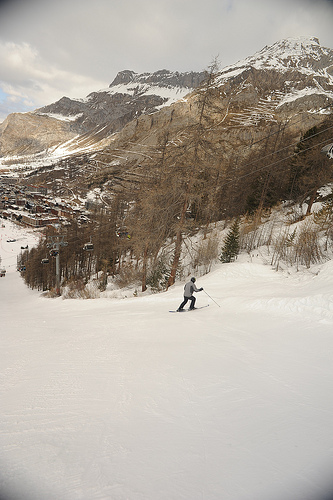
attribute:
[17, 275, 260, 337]
slope — ski  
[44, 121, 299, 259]
trees — Many 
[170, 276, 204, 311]
person — skiing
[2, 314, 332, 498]
slope — white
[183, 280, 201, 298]
jacket — gray, grey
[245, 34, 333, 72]
snow covered peaks — top 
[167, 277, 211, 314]
skier — skiing, man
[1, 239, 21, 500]
slope — steep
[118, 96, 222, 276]
leeves — lost their 